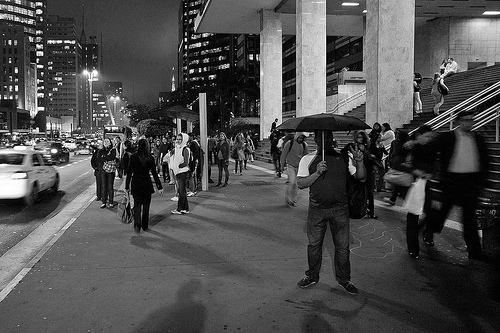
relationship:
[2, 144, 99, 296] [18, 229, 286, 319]
road with tarmac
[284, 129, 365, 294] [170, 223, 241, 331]
man standing on sidewalk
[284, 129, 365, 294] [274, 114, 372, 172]
man holding umbrella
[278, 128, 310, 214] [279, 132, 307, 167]
man wearing hoodie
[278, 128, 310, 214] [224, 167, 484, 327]
man walking down sidewalk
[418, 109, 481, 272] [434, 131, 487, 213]
man wearing suit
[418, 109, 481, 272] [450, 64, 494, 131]
man walking pass stairs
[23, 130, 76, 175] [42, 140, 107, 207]
vehicle traveling down road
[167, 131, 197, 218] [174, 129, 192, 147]
boy wearing hood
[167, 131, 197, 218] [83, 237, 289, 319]
boy standing on sidewalk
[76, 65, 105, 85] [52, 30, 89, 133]
street light beside building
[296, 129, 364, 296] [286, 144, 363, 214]
man in shirt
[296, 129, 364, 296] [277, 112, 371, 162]
man holding umbrella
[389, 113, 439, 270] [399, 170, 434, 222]
woman holding grocery bag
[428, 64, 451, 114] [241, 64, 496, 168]
woman walking up stairs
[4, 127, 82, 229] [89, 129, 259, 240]
cab passing by people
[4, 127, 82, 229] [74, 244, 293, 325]
cab on sidewalk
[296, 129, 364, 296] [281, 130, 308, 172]
man in hoodie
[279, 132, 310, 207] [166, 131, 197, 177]
man in hoodie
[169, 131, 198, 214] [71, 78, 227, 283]
boy waiting at bus stop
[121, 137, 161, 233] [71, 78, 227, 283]
people waiting at bus stop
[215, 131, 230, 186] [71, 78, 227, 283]
people waiting at bus stop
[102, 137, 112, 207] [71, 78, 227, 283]
people waiting at bus stop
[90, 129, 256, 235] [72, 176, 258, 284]
crowd on street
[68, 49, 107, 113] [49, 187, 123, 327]
lights shining above street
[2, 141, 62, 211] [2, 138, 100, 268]
taxi on street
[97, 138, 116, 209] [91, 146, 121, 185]
people has bag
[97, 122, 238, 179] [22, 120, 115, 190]
crowd on street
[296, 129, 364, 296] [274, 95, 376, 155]
man has an umbrella